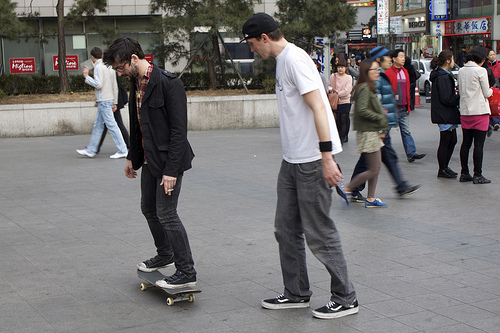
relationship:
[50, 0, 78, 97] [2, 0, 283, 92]
trunk front of building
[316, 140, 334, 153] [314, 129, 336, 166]
wristband on wrist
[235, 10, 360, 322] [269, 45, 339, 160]
male in shirt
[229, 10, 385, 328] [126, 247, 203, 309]
male watching skateboard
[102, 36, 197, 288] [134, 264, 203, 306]
male on skateboard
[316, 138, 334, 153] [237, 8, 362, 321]
wristband worn by male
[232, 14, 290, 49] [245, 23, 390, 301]
hat worn by male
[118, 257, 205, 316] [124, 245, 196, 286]
skateboard under feet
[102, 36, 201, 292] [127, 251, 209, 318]
male on skateboard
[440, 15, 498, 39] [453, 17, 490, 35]
sign with writing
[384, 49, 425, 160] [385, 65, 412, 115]
man wearing coat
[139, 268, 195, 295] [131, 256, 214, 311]
grip tape on board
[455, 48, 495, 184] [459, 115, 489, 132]
woman wearing pink skirt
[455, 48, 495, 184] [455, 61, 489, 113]
woman wearing white coat